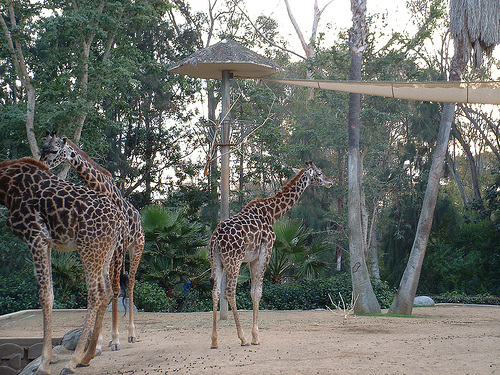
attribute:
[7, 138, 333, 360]
giraffes — tall, brown, skinny, wide, spotted, yellow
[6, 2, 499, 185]
sky — bright, white, light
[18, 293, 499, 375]
ground — dirty, brown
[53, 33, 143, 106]
leaves — green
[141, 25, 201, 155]
leaves — green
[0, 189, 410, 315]
bushes — gray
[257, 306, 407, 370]
dirt — tan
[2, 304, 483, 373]
enclosure — giraffe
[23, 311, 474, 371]
dirt — tan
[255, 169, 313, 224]
neck — long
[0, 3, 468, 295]
trees — green, gray, skinny, tall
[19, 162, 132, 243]
spots — brown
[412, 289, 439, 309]
rock — white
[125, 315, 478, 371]
ground — brown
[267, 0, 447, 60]
sky — white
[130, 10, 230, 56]
branch — tree branch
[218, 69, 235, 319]
beam — long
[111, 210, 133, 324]
tail — small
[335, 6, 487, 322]
tree — tall, old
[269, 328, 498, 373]
sand — tan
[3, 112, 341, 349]
giraffes — looking down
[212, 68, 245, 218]
pole — steel